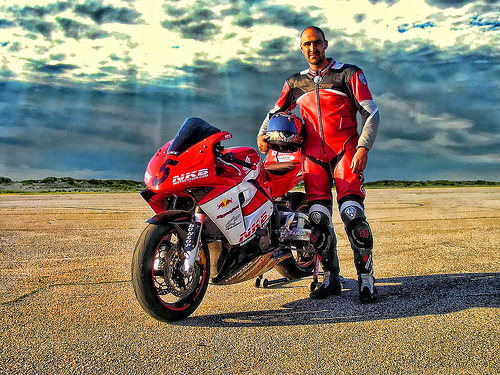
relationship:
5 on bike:
[155, 161, 178, 187] [131, 119, 349, 319]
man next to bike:
[253, 28, 389, 300] [131, 119, 349, 319]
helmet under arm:
[266, 112, 302, 149] [253, 79, 302, 148]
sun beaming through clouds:
[12, 0, 499, 77] [2, 0, 498, 40]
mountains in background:
[2, 169, 499, 195] [1, 0, 494, 196]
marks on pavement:
[230, 261, 499, 335] [2, 187, 496, 373]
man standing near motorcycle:
[253, 28, 389, 300] [131, 119, 349, 319]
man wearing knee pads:
[253, 28, 389, 300] [310, 199, 377, 249]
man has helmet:
[253, 28, 389, 300] [266, 112, 302, 149]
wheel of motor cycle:
[130, 218, 216, 321] [131, 119, 349, 319]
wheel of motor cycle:
[272, 191, 322, 278] [131, 119, 349, 319]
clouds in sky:
[2, 0, 498, 40] [1, 0, 494, 196]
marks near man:
[189, 271, 496, 329] [253, 28, 389, 300]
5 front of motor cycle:
[155, 161, 178, 187] [131, 119, 349, 319]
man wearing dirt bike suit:
[253, 28, 389, 300] [268, 61, 381, 309]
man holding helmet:
[253, 28, 389, 300] [266, 112, 302, 149]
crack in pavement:
[1, 272, 138, 310] [2, 187, 496, 373]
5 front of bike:
[155, 161, 178, 187] [131, 119, 349, 319]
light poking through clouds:
[12, 0, 499, 77] [2, 0, 498, 40]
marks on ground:
[189, 271, 496, 329] [2, 187, 496, 373]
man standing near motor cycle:
[253, 28, 389, 300] [131, 119, 349, 319]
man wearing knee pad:
[253, 28, 389, 300] [307, 198, 335, 263]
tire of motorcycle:
[130, 218, 216, 321] [131, 119, 349, 319]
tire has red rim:
[130, 218, 216, 321] [151, 230, 208, 310]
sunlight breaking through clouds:
[12, 0, 499, 77] [2, 0, 498, 40]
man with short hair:
[253, 28, 389, 300] [299, 26, 325, 39]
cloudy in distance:
[2, 2, 499, 79] [1, 0, 494, 196]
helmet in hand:
[266, 112, 302, 149] [258, 135, 271, 150]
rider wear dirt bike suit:
[253, 28, 389, 300] [268, 61, 381, 309]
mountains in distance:
[2, 169, 499, 195] [1, 0, 494, 196]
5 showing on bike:
[155, 161, 178, 187] [131, 119, 349, 319]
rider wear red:
[253, 28, 389, 300] [268, 61, 381, 309]